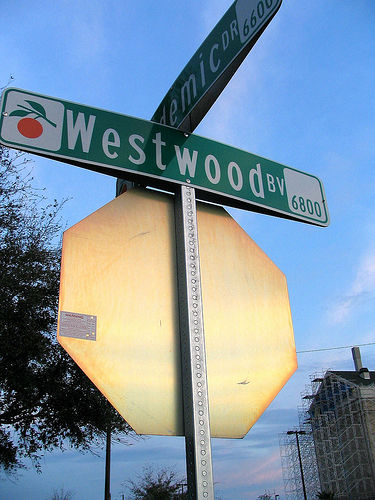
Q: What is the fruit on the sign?
A: Peach.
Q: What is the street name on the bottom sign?
A: Westwood.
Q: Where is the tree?
A: Behind the sign.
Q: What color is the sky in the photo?
A: Blue.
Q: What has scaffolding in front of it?
A: The building.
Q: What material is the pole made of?
A: Steel.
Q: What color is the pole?
A: Grey.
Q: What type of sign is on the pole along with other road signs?
A: Traffic sign.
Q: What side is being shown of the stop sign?
A: The back.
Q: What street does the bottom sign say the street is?
A: Westwood Bv.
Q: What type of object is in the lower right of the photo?
A: A Structure.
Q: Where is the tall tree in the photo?
A: The background.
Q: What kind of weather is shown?
A: Sunny day.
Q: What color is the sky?
A: Blue.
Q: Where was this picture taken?
A: The street corner.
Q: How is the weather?
A: Clear.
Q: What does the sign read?
A: Westwood.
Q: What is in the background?
A: A building.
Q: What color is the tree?
A: Green.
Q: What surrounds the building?
A: Scaffolding.